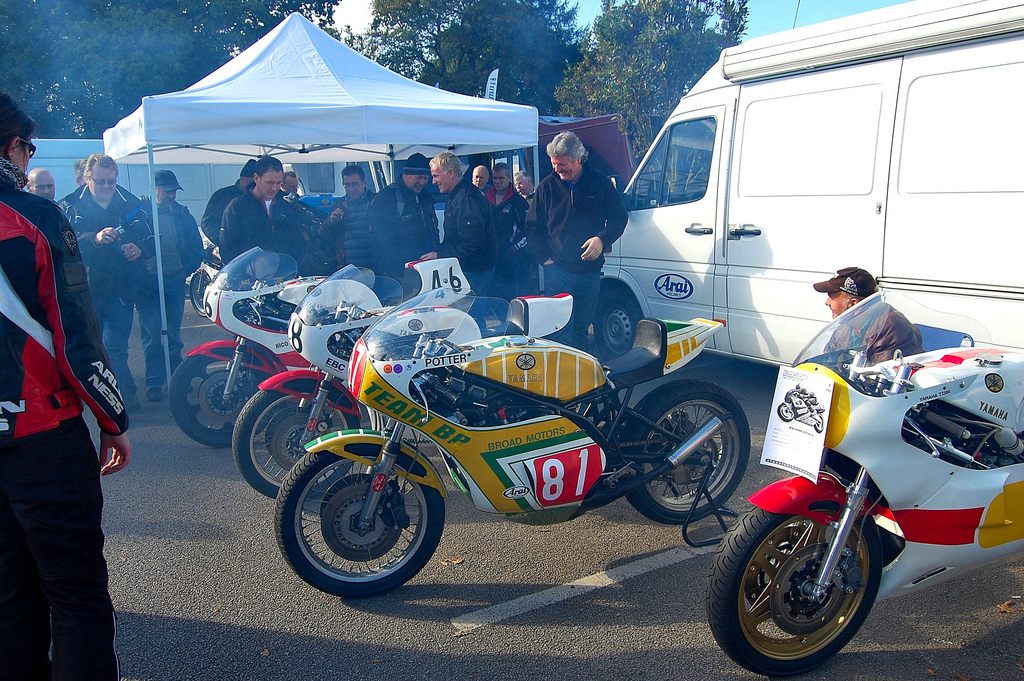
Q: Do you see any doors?
A: Yes, there is a door.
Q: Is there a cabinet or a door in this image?
A: Yes, there is a door.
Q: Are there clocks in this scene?
A: No, there are no clocks.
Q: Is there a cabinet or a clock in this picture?
A: No, there are no clocks or cabinets.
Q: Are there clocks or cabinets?
A: No, there are no clocks or cabinets.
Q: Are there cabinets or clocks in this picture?
A: No, there are no clocks or cabinets.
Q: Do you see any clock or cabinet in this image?
A: No, there are no clocks or cabinets.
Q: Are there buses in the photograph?
A: No, there are no buses.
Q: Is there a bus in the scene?
A: No, there are no buses.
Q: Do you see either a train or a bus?
A: No, there are no buses or trains.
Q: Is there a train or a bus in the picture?
A: No, there are no buses or trains.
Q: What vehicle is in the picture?
A: The vehicle is a van.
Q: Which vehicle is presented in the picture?
A: The vehicle is a van.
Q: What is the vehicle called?
A: The vehicle is a van.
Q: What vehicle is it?
A: The vehicle is a van.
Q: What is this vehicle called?
A: This is a van.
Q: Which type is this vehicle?
A: This is a van.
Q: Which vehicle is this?
A: This is a van.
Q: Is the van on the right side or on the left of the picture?
A: The van is on the right of the image.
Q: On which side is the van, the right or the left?
A: The van is on the right of the image.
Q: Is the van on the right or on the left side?
A: The van is on the right of the image.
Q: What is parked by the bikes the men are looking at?
A: The van is parked by the bikes.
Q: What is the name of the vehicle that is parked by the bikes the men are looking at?
A: The vehicle is a van.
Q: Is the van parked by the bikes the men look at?
A: Yes, the van is parked by the bikes.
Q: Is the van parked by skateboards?
A: No, the van is parked by the bikes.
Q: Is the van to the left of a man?
A: No, the van is to the right of a man.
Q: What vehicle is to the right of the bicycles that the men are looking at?
A: The vehicle is a van.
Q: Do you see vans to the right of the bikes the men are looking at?
A: Yes, there is a van to the right of the bikes.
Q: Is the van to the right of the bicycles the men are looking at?
A: Yes, the van is to the right of the bikes.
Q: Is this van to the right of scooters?
A: No, the van is to the right of the bikes.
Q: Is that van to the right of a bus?
A: No, the van is to the right of a bike.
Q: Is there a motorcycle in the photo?
A: Yes, there is a motorcycle.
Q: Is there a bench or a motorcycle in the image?
A: Yes, there is a motorcycle.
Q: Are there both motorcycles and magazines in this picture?
A: No, there is a motorcycle but no magazines.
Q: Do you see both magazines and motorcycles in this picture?
A: No, there is a motorcycle but no magazines.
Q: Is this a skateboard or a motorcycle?
A: This is a motorcycle.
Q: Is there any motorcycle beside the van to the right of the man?
A: Yes, there is a motorcycle beside the van.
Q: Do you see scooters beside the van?
A: No, there is a motorcycle beside the van.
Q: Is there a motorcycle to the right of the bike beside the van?
A: Yes, there is a motorcycle to the right of the bike.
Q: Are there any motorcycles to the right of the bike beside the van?
A: Yes, there is a motorcycle to the right of the bike.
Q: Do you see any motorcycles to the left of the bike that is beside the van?
A: No, the motorcycle is to the right of the bike.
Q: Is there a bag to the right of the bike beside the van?
A: No, there is a motorcycle to the right of the bike.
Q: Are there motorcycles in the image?
A: Yes, there is a motorcycle.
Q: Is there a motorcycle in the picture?
A: Yes, there is a motorcycle.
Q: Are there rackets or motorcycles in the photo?
A: Yes, there is a motorcycle.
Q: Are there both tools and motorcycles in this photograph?
A: No, there is a motorcycle but no tools.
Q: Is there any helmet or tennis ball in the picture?
A: No, there are no helmets or tennis balls.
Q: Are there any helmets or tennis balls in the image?
A: No, there are no helmets or tennis balls.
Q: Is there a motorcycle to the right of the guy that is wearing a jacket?
A: Yes, there is a motorcycle to the right of the guy.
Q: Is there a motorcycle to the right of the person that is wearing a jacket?
A: Yes, there is a motorcycle to the right of the guy.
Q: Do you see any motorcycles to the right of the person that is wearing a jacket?
A: Yes, there is a motorcycle to the right of the guy.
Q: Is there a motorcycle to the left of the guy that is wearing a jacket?
A: No, the motorcycle is to the right of the guy.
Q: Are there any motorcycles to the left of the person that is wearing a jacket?
A: No, the motorcycle is to the right of the guy.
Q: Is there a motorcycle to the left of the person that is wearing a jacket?
A: No, the motorcycle is to the right of the guy.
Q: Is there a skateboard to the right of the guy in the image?
A: No, there is a motorcycle to the right of the guy.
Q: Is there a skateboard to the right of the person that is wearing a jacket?
A: No, there is a motorcycle to the right of the guy.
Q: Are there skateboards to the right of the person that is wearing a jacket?
A: No, there is a motorcycle to the right of the guy.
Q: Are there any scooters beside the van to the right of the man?
A: No, there is a motorcycle beside the van.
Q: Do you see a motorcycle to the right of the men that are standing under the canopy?
A: Yes, there is a motorcycle to the right of the men.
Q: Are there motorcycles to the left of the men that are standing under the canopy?
A: No, the motorcycle is to the right of the men.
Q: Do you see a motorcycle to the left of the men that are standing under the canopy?
A: No, the motorcycle is to the right of the men.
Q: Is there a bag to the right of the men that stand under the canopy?
A: No, there is a motorcycle to the right of the men.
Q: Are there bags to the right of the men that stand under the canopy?
A: No, there is a motorcycle to the right of the men.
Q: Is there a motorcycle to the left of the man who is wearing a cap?
A: Yes, there is a motorcycle to the left of the man.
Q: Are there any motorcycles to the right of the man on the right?
A: No, the motorcycle is to the left of the man.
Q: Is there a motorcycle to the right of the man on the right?
A: No, the motorcycle is to the left of the man.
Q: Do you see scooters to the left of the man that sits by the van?
A: No, there is a motorcycle to the left of the man.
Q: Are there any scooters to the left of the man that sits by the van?
A: No, there is a motorcycle to the left of the man.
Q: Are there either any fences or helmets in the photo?
A: No, there are no helmets or fences.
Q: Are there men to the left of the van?
A: Yes, there is a man to the left of the van.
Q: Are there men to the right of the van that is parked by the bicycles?
A: No, the man is to the left of the van.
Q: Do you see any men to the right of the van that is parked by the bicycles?
A: No, the man is to the left of the van.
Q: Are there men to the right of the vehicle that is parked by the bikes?
A: No, the man is to the left of the van.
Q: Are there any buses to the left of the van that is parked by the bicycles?
A: No, there is a man to the left of the van.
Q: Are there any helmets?
A: No, there are no helmets.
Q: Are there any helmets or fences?
A: No, there are no helmets or fences.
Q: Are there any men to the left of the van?
A: Yes, there is a man to the left of the van.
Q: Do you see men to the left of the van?
A: Yes, there is a man to the left of the van.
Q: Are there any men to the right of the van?
A: No, the man is to the left of the van.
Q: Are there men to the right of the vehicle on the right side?
A: No, the man is to the left of the van.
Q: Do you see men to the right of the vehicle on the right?
A: No, the man is to the left of the van.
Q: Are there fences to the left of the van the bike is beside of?
A: No, there is a man to the left of the van.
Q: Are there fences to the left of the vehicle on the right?
A: No, there is a man to the left of the van.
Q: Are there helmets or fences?
A: No, there are no fences or helmets.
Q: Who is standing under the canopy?
A: The men are standing under the canopy.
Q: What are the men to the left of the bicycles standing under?
A: The men are standing under the canopy.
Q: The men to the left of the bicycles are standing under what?
A: The men are standing under the canopy.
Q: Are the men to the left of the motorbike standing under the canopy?
A: Yes, the men are standing under the canopy.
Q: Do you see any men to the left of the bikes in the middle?
A: Yes, there are men to the left of the bicycles.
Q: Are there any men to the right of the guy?
A: Yes, there are men to the right of the guy.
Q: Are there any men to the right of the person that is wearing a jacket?
A: Yes, there are men to the right of the guy.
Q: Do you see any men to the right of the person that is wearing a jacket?
A: Yes, there are men to the right of the guy.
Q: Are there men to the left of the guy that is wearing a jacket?
A: No, the men are to the right of the guy.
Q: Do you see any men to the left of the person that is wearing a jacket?
A: No, the men are to the right of the guy.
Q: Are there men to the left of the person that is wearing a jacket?
A: No, the men are to the right of the guy.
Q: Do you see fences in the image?
A: No, there are no fences.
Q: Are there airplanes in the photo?
A: No, there are no airplanes.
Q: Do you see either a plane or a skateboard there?
A: No, there are no airplanes or skateboards.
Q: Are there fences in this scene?
A: No, there are no fences.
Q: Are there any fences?
A: No, there are no fences.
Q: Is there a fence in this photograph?
A: No, there are no fences.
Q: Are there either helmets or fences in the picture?
A: No, there are no fences or helmets.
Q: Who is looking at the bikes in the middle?
A: The men are looking at the bicycles.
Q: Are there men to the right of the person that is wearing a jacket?
A: Yes, there are men to the right of the guy.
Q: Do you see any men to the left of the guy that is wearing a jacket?
A: No, the men are to the right of the guy.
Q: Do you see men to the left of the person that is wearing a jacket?
A: No, the men are to the right of the guy.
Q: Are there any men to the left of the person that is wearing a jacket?
A: No, the men are to the right of the guy.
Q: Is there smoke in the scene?
A: Yes, there is smoke.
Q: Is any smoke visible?
A: Yes, there is smoke.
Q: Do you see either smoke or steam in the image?
A: Yes, there is smoke.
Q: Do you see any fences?
A: No, there are no fences.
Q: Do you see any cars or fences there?
A: No, there are no fences or cars.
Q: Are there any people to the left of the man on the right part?
A: Yes, there are people to the left of the man.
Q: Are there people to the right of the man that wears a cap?
A: No, the people are to the left of the man.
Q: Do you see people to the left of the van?
A: Yes, there are people to the left of the van.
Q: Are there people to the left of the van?
A: Yes, there are people to the left of the van.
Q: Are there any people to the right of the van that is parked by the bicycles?
A: No, the people are to the left of the van.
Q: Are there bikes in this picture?
A: Yes, there are bikes.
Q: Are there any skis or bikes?
A: Yes, there are bikes.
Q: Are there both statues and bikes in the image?
A: No, there are bikes but no statues.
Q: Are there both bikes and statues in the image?
A: No, there are bikes but no statues.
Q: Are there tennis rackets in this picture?
A: No, there are no tennis rackets.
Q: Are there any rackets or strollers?
A: No, there are no rackets or strollers.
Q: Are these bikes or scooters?
A: These are bikes.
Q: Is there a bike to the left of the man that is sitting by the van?
A: Yes, there are bikes to the left of the man.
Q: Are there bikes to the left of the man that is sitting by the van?
A: Yes, there are bikes to the left of the man.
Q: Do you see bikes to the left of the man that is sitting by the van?
A: Yes, there are bikes to the left of the man.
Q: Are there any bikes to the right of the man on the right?
A: No, the bikes are to the left of the man.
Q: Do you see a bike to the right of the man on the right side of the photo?
A: No, the bikes are to the left of the man.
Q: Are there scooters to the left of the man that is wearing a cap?
A: No, there are bikes to the left of the man.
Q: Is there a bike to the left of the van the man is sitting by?
A: Yes, there are bikes to the left of the van.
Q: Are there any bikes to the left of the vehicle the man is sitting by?
A: Yes, there are bikes to the left of the van.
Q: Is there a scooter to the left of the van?
A: No, there are bikes to the left of the van.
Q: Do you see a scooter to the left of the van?
A: No, there are bikes to the left of the van.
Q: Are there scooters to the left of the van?
A: No, there are bikes to the left of the van.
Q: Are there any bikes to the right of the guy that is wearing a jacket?
A: Yes, there are bikes to the right of the guy.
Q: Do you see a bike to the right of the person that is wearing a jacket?
A: Yes, there are bikes to the right of the guy.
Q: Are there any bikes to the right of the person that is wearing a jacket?
A: Yes, there are bikes to the right of the guy.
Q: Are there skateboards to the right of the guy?
A: No, there are bikes to the right of the guy.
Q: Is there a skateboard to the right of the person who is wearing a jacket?
A: No, there are bikes to the right of the guy.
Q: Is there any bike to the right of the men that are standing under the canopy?
A: Yes, there are bikes to the right of the men.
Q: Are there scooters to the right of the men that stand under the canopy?
A: No, there are bikes to the right of the men.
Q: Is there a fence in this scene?
A: No, there are no fences.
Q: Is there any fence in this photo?
A: No, there are no fences.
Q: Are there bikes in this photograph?
A: Yes, there is a bike.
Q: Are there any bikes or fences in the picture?
A: Yes, there is a bike.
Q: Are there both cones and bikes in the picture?
A: No, there is a bike but no cones.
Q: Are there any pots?
A: No, there are no pots.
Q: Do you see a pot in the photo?
A: No, there are no pots.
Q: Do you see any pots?
A: No, there are no pots.